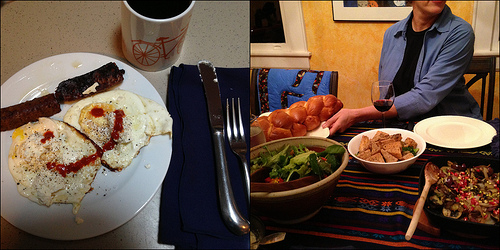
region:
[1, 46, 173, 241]
white plate of eggs and sausage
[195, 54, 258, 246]
utensils on a black napkin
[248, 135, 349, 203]
bowl containing green vegetables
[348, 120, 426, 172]
white bowl of food on a cloth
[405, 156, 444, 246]
wooden spoon on a table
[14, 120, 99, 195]
eggs with a red sauce on it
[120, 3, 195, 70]
cup on a counter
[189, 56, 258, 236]
silver knife and fork on a napkin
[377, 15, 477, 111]
blue and black tops on a person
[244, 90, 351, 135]
large loaf of bread on a white plate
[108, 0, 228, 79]
coffee mug on counter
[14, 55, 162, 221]
eggs and sausage on plate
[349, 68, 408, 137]
glass of wine on table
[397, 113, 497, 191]
white plate on table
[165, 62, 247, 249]
fork and knife on napkin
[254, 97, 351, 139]
pull-apart rolls on plate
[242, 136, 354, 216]
green salad in bowl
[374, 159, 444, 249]
wood serving utensil on table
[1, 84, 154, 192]
two eyes and smile on eggs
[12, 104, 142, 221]
pepper on top of eggs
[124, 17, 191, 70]
Red bike on mug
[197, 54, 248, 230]
Silver knife next to fork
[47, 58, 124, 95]
Sausage next to egg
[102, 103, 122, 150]
Red sauce drizzled on egg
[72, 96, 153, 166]
Egg on round white plate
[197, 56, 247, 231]
Knife on blue napkin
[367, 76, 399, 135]
Wine glass in front of person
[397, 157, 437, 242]
Wooden spoon resting in black tray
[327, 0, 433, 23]
Art work behind woman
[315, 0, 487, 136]
Person sitting on wooden chair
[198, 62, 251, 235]
Fork and butter knife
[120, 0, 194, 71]
Red bicycle on white coffee cup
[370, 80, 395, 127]
Glass of red wine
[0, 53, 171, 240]
Two fried eggs and two sausage links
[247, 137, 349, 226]
Brown bowl filled with salad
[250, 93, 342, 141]
Braided dinner bread loaf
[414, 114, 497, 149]
Empty white porcelain dinner plate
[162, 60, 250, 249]
Knife and fork sitting on blue cloth napkin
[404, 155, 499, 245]
Vegetable dinner entree with wooden spoon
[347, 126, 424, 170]
White bowl filled with brown bread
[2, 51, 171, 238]
white plate holding food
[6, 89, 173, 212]
two eggs on white plate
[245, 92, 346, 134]
hand holding platter of bread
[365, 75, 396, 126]
glass of red wine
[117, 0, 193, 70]
coffee in paper cup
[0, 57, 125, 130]
two sausages on plate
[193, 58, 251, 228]
silver fork and knife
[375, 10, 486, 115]
lady wearing blue shirt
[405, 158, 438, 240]
brown wooden spoon in dish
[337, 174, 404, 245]
brown stripped table cloth